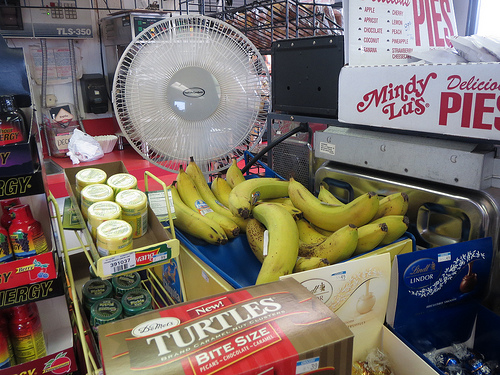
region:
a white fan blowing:
[105, 10, 259, 188]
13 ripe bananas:
[172, 156, 399, 271]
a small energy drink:
[5, 175, 65, 300]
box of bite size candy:
[65, 280, 342, 361]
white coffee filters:
[80, 127, 116, 152]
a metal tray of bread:
[197, 0, 332, 40]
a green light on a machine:
[26, 6, 52, 13]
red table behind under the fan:
[40, 130, 165, 185]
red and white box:
[345, 0, 496, 115]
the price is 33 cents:
[280, 350, 323, 370]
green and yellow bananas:
[170, 158, 415, 266]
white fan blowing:
[111, 15, 273, 169]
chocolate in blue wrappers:
[427, 337, 498, 374]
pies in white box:
[342, 2, 498, 128]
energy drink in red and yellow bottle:
[10, 202, 50, 258]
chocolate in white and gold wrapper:
[355, 350, 395, 372]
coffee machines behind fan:
[100, 11, 205, 57]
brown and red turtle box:
[100, 278, 350, 373]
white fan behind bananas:
[125, 16, 262, 189]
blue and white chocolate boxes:
[281, 257, 493, 372]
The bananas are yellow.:
[170, 157, 416, 282]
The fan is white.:
[105, 11, 270, 192]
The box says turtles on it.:
[98, 290, 326, 367]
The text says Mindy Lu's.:
[342, 70, 437, 126]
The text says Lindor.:
[400, 261, 440, 286]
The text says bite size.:
[170, 315, 287, 373]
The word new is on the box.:
[185, 295, 230, 315]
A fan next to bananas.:
[106, 20, 286, 245]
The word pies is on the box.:
[435, 81, 496, 134]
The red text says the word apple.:
[352, 3, 385, 18]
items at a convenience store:
[5, 9, 496, 373]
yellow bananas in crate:
[180, 163, 415, 269]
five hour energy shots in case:
[2, 117, 80, 374]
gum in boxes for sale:
[54, 159, 191, 326]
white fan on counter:
[109, 7, 285, 187]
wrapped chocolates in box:
[424, 342, 491, 373]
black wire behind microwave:
[239, 120, 311, 172]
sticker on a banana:
[193, 195, 212, 218]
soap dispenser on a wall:
[72, 65, 115, 119]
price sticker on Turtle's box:
[285, 352, 332, 373]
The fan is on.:
[104, 2, 270, 169]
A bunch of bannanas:
[179, 156, 405, 263]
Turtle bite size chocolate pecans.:
[94, 276, 354, 373]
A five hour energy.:
[3, 202, 50, 256]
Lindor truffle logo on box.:
[402, 258, 442, 292]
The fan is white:
[111, 14, 271, 170]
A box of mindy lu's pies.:
[339, 0, 499, 141]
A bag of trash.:
[66, 130, 106, 165]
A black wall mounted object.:
[77, 69, 109, 117]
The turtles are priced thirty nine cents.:
[296, 359, 320, 371]